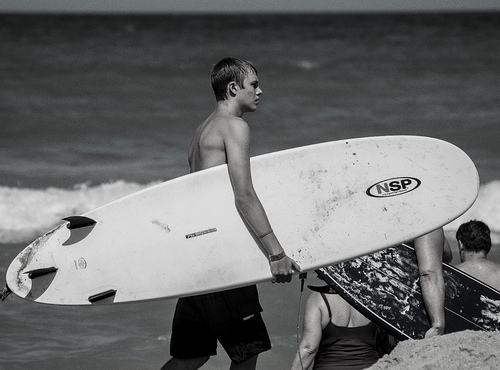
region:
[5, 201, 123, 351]
three small fins on back of surfboard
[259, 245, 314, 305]
man is wearing safety strap for surfboard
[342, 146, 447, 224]
surfboad has NSP on the bottom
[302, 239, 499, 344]
person carrying a surfboard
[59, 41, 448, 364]
picture taken in black and white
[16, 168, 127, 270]
wave in the water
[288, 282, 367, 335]
strap of woman's bathing suit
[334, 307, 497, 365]
pile of sand on the beach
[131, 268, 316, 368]
man is wearing a bathing trunks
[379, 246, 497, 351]
surfboard is a dark color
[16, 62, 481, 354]
Man walking with his surfboard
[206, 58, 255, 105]
Man has blonde hair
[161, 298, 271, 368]
Surfer is wearing black shorts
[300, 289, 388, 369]
Woman is wearing a black bathing suit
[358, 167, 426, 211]
The letters NSP are written on surf board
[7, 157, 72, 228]
Small wave in the ocean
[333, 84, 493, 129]
Ocean is a little choppy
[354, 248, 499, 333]
Person holding black surfboard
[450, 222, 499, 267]
Man has dark brown hair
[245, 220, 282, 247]
Man is wearing black arm band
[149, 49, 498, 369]
two surfers, one young, thin, blond, visible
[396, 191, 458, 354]
the other, shorter, thicker, almost unseen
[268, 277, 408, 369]
pass a middle aged woman wearing wrinkled dark tank suit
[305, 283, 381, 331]
shoulder blades unmistakable, her head is hidden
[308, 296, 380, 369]
her strap is thin, vertical middle of suit sheer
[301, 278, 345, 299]
a surfboard's fin obscures most of her face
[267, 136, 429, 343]
the crossing of a mucky white & marbled dark surfboard cover the rest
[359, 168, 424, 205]
'nsp' in an oval among the footprints from which came the mud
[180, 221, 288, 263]
two wristbands on a wrist, an unintelligible word @ mid-board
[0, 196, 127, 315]
a slice of leash, a little logo, three fins, two shadows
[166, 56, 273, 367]
a shirtless young man standing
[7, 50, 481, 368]
a man carrying a surfboard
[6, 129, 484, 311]
a white surfboard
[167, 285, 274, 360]
a pair of men's black shorts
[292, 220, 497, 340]
a black surfboard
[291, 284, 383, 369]
a woman in a tank top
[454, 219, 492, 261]
a man's head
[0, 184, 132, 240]
a crashing white wave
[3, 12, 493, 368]
a body of water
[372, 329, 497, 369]
a mound of beach sand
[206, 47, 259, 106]
the man has short hair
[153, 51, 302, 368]
the man is shirtless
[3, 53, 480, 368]
the man is carrying a surfboard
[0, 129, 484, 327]
the surfboard is light colored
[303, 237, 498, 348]
the surfboard is dark colored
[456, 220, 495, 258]
the man has dark hair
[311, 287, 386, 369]
the woman is wearing a black bathingsuit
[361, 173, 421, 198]
the surfboard has a logo on it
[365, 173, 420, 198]
the logo says nsp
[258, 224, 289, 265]
the man is wearing a bracelet